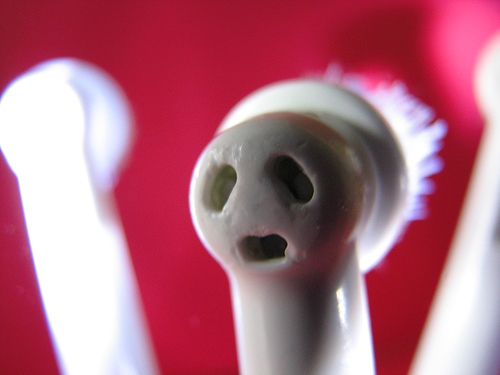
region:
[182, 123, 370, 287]
the end of a electric toothbrush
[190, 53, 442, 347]
a white electric tooth brush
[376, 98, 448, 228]
bristle on a tooth brush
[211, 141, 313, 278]
opening on a electric toothbrush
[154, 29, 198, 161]
a red back ground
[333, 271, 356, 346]
a reflection on the side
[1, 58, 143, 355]
a white shaped object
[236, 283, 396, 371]
a shadow on the tooth brush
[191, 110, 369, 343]
a electric tooth brush with a opening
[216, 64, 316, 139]
the rim of a eletric tooth brush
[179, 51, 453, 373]
back of round brush, shot to resemble face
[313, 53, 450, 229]
round white bristles turning to blue @ the tips from the light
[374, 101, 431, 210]
light hitting the bristles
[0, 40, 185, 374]
a different brush, blurred as supporting cast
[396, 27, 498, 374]
another brush, only half of it, blurred for same reason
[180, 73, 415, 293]
featured brush has round front end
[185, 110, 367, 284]
featured brush has round back end, but smaller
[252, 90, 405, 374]
shadows to the right on brush, cut by a blade of reflection from light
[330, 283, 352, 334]
the blade of reflection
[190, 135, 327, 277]
a bumpy plastic face, created by light+shadow+positioning+imagination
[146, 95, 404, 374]
This is a cray model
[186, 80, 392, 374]
a white cray model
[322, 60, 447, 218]
bristles on a white brush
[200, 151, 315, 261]
three oblong holes in the brush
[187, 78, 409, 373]
ceramic off white brush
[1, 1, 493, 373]
red cloth behind the brushes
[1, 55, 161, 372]
blurry white object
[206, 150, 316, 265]
three holes look like a face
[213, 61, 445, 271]
bristles on a round head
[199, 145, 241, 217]
oval hole with some chips around it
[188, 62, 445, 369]
off white spin brush head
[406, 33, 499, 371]
blurry object on the right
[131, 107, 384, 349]
This is a toothbrush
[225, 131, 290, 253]
These are three holes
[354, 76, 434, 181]
This is a white brush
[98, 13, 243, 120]
The background is red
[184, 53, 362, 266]
The brush is made of plastic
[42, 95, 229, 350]
These are two tooth brushes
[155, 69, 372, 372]
The toothbrush is electric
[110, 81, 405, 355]
The light is shining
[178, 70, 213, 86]
The color is lipstick red